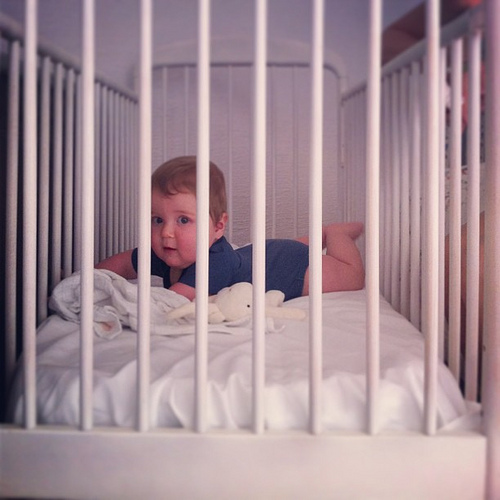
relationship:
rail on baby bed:
[22, 0, 39, 429] [0, 1, 484, 496]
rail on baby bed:
[367, 0, 385, 433] [0, 1, 484, 496]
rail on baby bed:
[309, 0, 324, 432] [0, 1, 484, 496]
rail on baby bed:
[420, 1, 439, 436] [0, 1, 484, 496]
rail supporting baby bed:
[249, 0, 267, 434] [0, 1, 484, 496]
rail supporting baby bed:
[192, 0, 211, 431] [0, 1, 484, 496]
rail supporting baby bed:
[134, 0, 151, 430] [0, 1, 484, 496]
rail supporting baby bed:
[3, 39, 20, 393] [0, 1, 484, 496]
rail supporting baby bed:
[37, 54, 48, 331] [0, 1, 484, 496]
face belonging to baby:
[151, 186, 198, 268] [92, 153, 365, 300]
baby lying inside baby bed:
[92, 153, 365, 300] [0, 1, 484, 496]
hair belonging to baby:
[152, 154, 230, 228] [92, 153, 365, 300]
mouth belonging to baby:
[160, 244, 179, 253] [92, 153, 365, 300]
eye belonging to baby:
[175, 213, 191, 225] [92, 153, 365, 300]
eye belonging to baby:
[153, 217, 164, 225] [92, 153, 365, 300]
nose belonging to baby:
[157, 215, 176, 239] [92, 153, 365, 300]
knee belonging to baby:
[346, 261, 366, 291] [92, 153, 365, 300]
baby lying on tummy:
[93, 154, 364, 302] [245, 279, 295, 302]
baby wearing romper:
[93, 154, 364, 302] [130, 233, 310, 303]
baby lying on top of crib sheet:
[93, 154, 364, 302] [7, 272, 482, 434]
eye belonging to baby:
[153, 217, 164, 225] [93, 154, 364, 302]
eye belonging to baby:
[177, 216, 191, 226] [93, 154, 364, 302]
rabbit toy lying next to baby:
[164, 280, 309, 323] [93, 154, 364, 302]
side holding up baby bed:
[1, 12, 141, 420] [0, 1, 484, 496]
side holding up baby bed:
[2, 2, 482, 498] [0, 1, 484, 496]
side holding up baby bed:
[342, 2, 484, 401] [0, 1, 484, 496]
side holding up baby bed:
[133, 29, 344, 248] [0, 1, 484, 496]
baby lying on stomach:
[93, 154, 364, 302] [244, 278, 303, 302]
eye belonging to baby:
[152, 215, 165, 225] [93, 154, 364, 302]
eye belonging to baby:
[173, 214, 192, 224] [93, 154, 364, 302]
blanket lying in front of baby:
[45, 265, 288, 342] [92, 153, 365, 300]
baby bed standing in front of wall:
[0, 1, 484, 496] [2, 2, 426, 323]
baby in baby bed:
[93, 154, 364, 302] [0, 1, 484, 496]